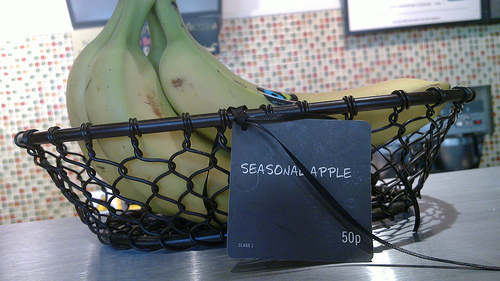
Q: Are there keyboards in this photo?
A: No, there are no keyboards.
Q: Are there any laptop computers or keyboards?
A: No, there are no keyboards or laptop computers.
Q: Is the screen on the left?
A: Yes, the screen is on the left of the image.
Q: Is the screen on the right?
A: No, the screen is on the left of the image.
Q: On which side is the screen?
A: The screen is on the left of the image.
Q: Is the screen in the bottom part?
A: No, the screen is in the top of the image.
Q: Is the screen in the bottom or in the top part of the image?
A: The screen is in the top of the image.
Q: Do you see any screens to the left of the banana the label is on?
A: Yes, there is a screen to the left of the banana.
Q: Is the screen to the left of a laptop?
A: No, the screen is to the left of the banana.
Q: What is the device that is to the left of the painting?
A: The device is a screen.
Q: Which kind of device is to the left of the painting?
A: The device is a screen.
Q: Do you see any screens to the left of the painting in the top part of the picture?
A: Yes, there is a screen to the left of the painting.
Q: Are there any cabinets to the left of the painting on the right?
A: No, there is a screen to the left of the painting.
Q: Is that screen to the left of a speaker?
A: No, the screen is to the left of the painting.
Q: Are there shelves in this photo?
A: No, there are no shelves.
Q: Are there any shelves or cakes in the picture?
A: No, there are no shelves or cakes.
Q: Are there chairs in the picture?
A: No, there are no chairs.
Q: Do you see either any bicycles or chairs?
A: No, there are no chairs or bicycles.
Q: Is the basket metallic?
A: Yes, the basket is metallic.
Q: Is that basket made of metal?
A: Yes, the basket is made of metal.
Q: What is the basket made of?
A: The basket is made of metal.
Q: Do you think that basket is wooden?
A: No, the basket is metallic.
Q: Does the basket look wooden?
A: No, the basket is metallic.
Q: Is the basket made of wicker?
A: No, the basket is made of metal.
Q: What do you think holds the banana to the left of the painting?
A: The basket holds the banana.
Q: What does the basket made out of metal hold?
A: The basket holds the banana.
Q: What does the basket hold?
A: The basket holds the banana.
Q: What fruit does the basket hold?
A: The basket holds the banana.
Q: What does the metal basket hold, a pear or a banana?
A: The basket holds a banana.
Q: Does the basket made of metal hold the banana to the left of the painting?
A: Yes, the basket holds the banana.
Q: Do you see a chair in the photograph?
A: No, there are no chairs.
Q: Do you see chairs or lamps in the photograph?
A: No, there are no chairs or lamps.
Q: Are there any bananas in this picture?
A: Yes, there is a banana.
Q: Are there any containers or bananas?
A: Yes, there is a banana.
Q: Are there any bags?
A: No, there are no bags.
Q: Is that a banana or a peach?
A: That is a banana.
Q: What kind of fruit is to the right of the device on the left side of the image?
A: The fruit is a banana.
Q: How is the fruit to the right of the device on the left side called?
A: The fruit is a banana.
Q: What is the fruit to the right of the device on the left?
A: The fruit is a banana.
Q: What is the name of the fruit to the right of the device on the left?
A: The fruit is a banana.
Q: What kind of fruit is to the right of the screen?
A: The fruit is a banana.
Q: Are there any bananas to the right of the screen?
A: Yes, there is a banana to the right of the screen.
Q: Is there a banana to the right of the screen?
A: Yes, there is a banana to the right of the screen.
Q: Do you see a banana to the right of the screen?
A: Yes, there is a banana to the right of the screen.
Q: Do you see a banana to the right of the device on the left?
A: Yes, there is a banana to the right of the screen.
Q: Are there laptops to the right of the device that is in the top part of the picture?
A: No, there is a banana to the right of the screen.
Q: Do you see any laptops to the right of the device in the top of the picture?
A: No, there is a banana to the right of the screen.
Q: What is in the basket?
A: The banana is in the basket.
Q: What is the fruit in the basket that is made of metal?
A: The fruit is a banana.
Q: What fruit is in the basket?
A: The fruit is a banana.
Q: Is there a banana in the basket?
A: Yes, there is a banana in the basket.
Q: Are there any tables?
A: Yes, there is a table.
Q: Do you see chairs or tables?
A: Yes, there is a table.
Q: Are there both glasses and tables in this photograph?
A: No, there is a table but no glasses.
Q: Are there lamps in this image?
A: No, there are no lamps.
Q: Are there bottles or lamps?
A: No, there are no lamps or bottles.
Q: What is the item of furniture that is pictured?
A: The piece of furniture is a table.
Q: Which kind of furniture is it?
A: The piece of furniture is a table.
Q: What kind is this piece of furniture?
A: This is a table.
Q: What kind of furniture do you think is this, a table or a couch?
A: This is a table.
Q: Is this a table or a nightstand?
A: This is a table.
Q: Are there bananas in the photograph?
A: Yes, there is a banana.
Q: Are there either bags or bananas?
A: Yes, there is a banana.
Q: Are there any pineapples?
A: No, there are no pineapples.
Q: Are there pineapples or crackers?
A: No, there are no pineapples or crackers.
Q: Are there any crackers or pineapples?
A: No, there are no pineapples or crackers.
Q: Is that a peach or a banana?
A: That is a banana.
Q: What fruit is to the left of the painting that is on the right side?
A: The fruit is a banana.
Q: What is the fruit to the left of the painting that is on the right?
A: The fruit is a banana.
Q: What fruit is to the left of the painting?
A: The fruit is a banana.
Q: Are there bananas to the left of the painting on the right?
A: Yes, there is a banana to the left of the painting.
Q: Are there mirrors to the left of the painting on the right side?
A: No, there is a banana to the left of the painting.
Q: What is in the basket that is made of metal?
A: The banana is in the basket.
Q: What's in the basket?
A: The banana is in the basket.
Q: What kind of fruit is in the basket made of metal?
A: The fruit is a banana.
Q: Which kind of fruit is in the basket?
A: The fruit is a banana.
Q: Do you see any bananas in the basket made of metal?
A: Yes, there is a banana in the basket.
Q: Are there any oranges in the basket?
A: No, there is a banana in the basket.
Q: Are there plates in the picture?
A: No, there are no plates.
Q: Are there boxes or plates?
A: No, there are no plates or boxes.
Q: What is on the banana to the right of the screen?
A: The label is on the banana.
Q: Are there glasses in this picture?
A: No, there are no glasses.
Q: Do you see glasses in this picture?
A: No, there are no glasses.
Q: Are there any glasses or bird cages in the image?
A: No, there are no glasses or bird cages.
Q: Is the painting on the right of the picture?
A: Yes, the painting is on the right of the image.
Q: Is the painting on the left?
A: No, the painting is on the right of the image.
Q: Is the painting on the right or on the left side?
A: The painting is on the right of the image.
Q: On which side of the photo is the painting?
A: The painting is on the right of the image.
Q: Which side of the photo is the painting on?
A: The painting is on the right of the image.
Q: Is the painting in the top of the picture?
A: Yes, the painting is in the top of the image.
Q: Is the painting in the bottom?
A: No, the painting is in the top of the image.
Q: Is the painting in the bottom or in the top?
A: The painting is in the top of the image.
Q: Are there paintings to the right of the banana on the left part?
A: Yes, there is a painting to the right of the banana.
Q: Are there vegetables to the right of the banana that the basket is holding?
A: No, there is a painting to the right of the banana.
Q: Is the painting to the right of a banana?
A: Yes, the painting is to the right of a banana.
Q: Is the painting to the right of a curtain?
A: No, the painting is to the right of a banana.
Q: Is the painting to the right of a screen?
A: Yes, the painting is to the right of a screen.